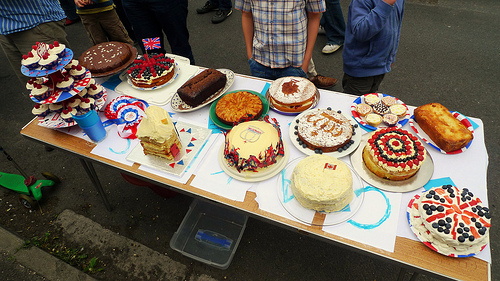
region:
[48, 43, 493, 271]
a long table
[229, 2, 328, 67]
a person standing in front of the table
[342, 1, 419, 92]
a person wearing a blue shirt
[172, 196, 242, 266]
a plastic box under the table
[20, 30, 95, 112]
a platter of cupcakes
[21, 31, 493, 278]
a table with cakes on it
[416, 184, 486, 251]
a cake with blueberries and strawberries on it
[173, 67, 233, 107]
a brown cake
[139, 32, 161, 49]
a flag on the cake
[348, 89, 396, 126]
a plate of cupcakes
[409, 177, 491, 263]
the cake on the table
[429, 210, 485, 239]
the black balls on the cake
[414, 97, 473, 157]
the bread on the table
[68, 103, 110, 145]
the blue item onthe table top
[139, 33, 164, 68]
the flag in the cake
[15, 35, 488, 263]
the cake on the table top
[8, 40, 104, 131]
the stack of platters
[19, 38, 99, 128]
the muffins stacked on the platter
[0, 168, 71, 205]
the green base of the scooter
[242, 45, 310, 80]
the hands in the jean pockets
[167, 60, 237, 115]
Brown dessert loaf on a oval plate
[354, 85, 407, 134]
Plate of iced cookies with sprinkles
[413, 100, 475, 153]
Yellow dessert loaf on colorful plate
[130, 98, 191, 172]
Portion of a white layered cake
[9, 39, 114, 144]
Tower of chocolate cupcakes with white icing and berries on top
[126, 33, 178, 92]
Cake with berries and a British flag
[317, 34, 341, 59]
Tip of a white shoe on the ground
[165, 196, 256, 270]
Plastic container with a blue label on the bottom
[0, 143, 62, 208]
Green scooter base on the ground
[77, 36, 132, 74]
Round chocolate cake with white sprinkles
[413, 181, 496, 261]
a cake with blueberries and red stripes on white icing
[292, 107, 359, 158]
a cake with a crown on top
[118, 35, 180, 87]
a red, white, and blue cake with a flag on top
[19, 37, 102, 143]
a tower of cupcakes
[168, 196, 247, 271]
a clear plastic tote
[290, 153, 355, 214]
a white cake on a clear plate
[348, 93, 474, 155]
two red, white, and blue plates with cakes on them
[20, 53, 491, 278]
a wooden table full of pastries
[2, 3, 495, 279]
a gray pavement surface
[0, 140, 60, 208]
a green colored scooter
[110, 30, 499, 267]
pastries on brown table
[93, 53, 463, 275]
white paper under plates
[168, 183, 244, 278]
clear tote under table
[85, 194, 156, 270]
concrete is dark grey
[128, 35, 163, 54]
UK flag on cake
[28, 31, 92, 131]
cupcakes arranged on stand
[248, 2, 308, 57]
blue and white shirt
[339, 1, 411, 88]
person has blue hoodie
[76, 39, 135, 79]
dark brown iced cake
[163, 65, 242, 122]
brown cake on oval plate